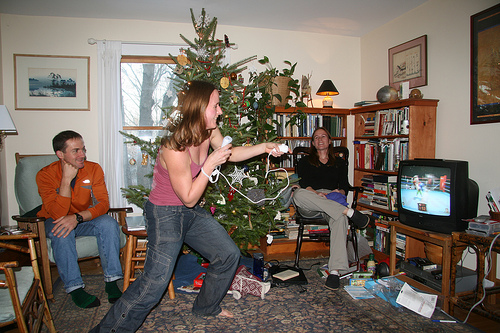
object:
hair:
[161, 80, 217, 151]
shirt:
[147, 139, 210, 207]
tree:
[117, 7, 311, 261]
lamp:
[316, 80, 340, 110]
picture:
[388, 33, 427, 92]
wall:
[361, 0, 500, 280]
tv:
[396, 157, 479, 235]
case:
[396, 158, 480, 233]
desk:
[387, 220, 500, 317]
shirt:
[36, 161, 110, 218]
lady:
[87, 80, 292, 332]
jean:
[88, 199, 242, 332]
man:
[36, 130, 127, 308]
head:
[53, 130, 87, 169]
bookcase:
[262, 99, 438, 262]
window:
[119, 62, 188, 128]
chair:
[10, 151, 136, 299]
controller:
[217, 134, 233, 150]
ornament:
[220, 75, 229, 90]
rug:
[41, 252, 478, 332]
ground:
[50, 249, 500, 332]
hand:
[264, 143, 288, 159]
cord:
[202, 150, 291, 203]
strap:
[199, 167, 212, 179]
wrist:
[203, 155, 215, 176]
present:
[232, 266, 275, 301]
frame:
[13, 53, 91, 112]